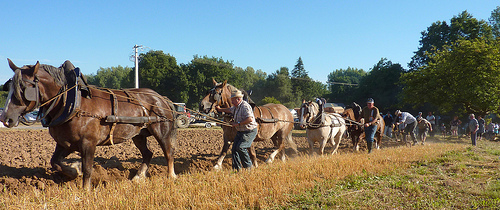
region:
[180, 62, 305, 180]
a light brown horse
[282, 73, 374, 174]
a white and brown horse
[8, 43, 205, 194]
a dark brown horse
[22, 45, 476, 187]
horse connected together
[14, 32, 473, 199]
horses are in a row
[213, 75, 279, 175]
man next to horse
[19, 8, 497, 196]
a bright and clear day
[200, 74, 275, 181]
a man beside the horse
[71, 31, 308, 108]
the trees are visible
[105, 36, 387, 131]
the trees are visible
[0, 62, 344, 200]
three horses walking in a row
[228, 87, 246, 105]
a man wearing a hat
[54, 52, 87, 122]
a harness on a horse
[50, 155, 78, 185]
a horse with it's foot raised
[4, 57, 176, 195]
a brown horse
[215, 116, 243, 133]
a man holding onto ropes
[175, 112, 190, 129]
a tire on a tractor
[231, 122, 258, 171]
a man wearing blue jeans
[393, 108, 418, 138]
a man bent over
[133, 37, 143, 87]
a wood electrical pole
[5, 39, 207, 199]
this is a horse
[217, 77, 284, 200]
man next to the horses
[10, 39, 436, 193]
horses are connected together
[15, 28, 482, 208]
horses are in a field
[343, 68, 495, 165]
group of people next to the horses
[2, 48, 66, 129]
horse wearing a bridle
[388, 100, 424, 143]
man is bent down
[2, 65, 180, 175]
the horse is brown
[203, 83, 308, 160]
the horse is brown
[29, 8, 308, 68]
the sky is clear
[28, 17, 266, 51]
the sky is clear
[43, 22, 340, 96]
the sky is clear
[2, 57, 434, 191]
horses plowing up a field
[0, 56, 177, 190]
dark brown lead horse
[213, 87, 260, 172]
man guiding horse